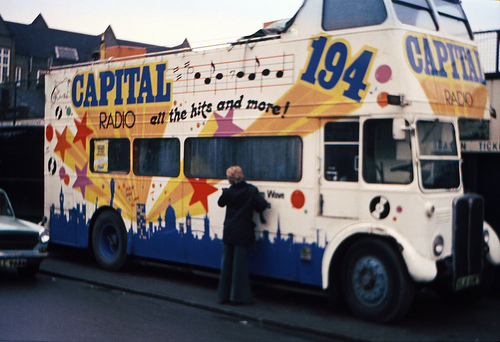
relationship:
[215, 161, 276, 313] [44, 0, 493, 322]
person by bus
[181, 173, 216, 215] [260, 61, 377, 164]
star on bus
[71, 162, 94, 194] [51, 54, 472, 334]
star on bus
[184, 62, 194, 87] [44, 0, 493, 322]
music note on bus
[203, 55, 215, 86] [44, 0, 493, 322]
music note on bus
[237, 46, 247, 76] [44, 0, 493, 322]
music note on bus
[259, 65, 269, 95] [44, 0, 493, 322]
music note on bus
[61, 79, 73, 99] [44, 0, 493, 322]
music note on bus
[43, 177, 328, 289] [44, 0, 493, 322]
buildings painted on bus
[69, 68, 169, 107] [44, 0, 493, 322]
letters painted on bus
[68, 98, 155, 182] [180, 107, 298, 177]
sign in window